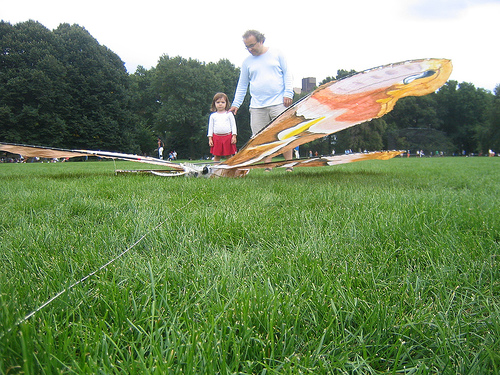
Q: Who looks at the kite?
A: A man with a small child.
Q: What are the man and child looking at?
A: A kite on the ground.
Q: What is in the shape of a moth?
A: The kite.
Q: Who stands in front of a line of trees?
A: A group of people.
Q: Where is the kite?
A: On the grass.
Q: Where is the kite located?
A: Outdoors on a grassy field.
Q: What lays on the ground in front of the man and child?
A: A kite.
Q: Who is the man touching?
A: A child.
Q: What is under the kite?
A: Grass.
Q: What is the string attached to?
A: A kite.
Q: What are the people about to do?
A: Fly a kite.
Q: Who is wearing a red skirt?
A: Little girl.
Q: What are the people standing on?
A: Grass.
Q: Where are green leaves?
A: On many trees.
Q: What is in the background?
A: Trees.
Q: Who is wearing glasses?
A: The man.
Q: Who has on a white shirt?
A: The girl.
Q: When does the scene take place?
A: During the daytime.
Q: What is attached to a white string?
A: Kite.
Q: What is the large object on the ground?
A: A kite.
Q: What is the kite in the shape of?
A: A butterfly.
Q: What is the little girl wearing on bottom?
A: A red skirt.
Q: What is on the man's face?
A: Eyeglasses.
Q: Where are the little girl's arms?
A: At her sides.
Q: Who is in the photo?
A: People.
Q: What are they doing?
A: Standing.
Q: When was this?
A: Daytime.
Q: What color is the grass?
A: Green.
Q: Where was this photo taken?
A: In a field.